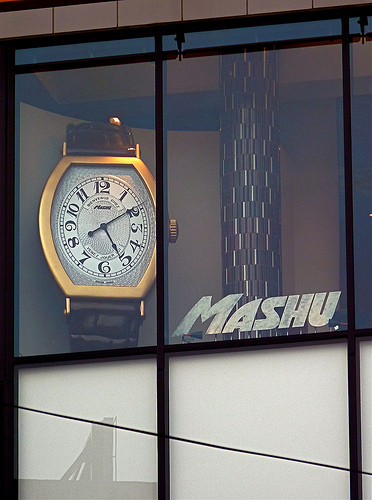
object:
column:
[220, 49, 284, 337]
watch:
[38, 120, 180, 352]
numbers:
[64, 178, 143, 274]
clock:
[36, 150, 174, 302]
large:
[39, 120, 179, 344]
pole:
[220, 34, 283, 348]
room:
[10, 47, 372, 356]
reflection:
[15, 415, 158, 499]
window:
[153, 23, 346, 350]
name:
[167, 292, 346, 334]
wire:
[11, 404, 369, 477]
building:
[1, 2, 371, 499]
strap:
[63, 123, 138, 155]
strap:
[70, 309, 139, 349]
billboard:
[60, 417, 119, 481]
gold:
[39, 188, 62, 256]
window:
[14, 346, 162, 499]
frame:
[4, 6, 357, 366]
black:
[98, 213, 108, 235]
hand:
[89, 201, 142, 258]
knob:
[168, 219, 178, 243]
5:
[118, 251, 131, 267]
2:
[126, 205, 142, 219]